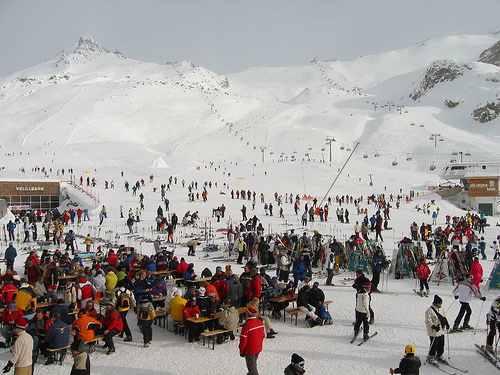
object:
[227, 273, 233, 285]
person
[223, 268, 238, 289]
blue jacket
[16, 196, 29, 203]
windows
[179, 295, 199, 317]
person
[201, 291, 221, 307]
person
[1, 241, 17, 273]
person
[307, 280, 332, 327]
person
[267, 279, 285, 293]
person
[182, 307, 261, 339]
table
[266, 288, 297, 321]
table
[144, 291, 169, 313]
table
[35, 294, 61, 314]
table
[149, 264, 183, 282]
table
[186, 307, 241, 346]
picnic table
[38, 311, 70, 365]
man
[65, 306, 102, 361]
person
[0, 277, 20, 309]
person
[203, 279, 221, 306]
person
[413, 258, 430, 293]
person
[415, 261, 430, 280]
jacket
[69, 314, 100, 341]
jacket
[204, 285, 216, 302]
jacket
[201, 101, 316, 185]
man skiing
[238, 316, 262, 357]
coat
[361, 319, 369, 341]
leg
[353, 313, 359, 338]
leg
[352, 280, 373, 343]
man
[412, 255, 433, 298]
people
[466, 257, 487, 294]
people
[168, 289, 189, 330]
people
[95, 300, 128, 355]
people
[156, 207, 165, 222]
people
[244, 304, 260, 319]
hat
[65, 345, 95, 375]
people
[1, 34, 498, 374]
ski slope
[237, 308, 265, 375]
man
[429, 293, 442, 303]
hat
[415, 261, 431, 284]
red jacket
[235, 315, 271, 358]
red jacket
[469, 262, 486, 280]
red jacket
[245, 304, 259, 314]
head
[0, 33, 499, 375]
snow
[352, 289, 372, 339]
outfit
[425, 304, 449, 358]
outfit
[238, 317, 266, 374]
outfit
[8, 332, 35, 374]
outfit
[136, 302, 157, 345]
outfit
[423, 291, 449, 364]
man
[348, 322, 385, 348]
skis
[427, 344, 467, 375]
skis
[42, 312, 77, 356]
person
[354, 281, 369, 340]
jacket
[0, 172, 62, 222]
brick building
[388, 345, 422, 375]
people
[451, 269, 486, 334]
people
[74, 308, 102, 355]
man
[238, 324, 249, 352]
arm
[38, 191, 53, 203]
window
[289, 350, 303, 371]
head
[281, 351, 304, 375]
person